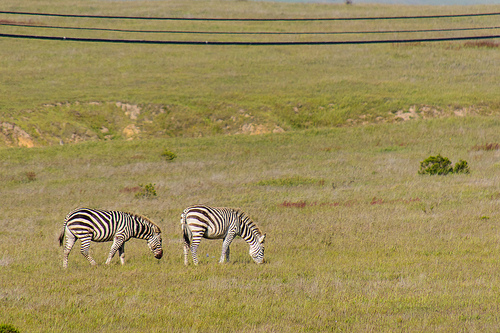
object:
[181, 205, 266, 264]
zebra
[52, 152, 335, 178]
grass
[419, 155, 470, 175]
bush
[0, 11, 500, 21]
line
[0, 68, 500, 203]
field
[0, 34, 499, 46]
lines